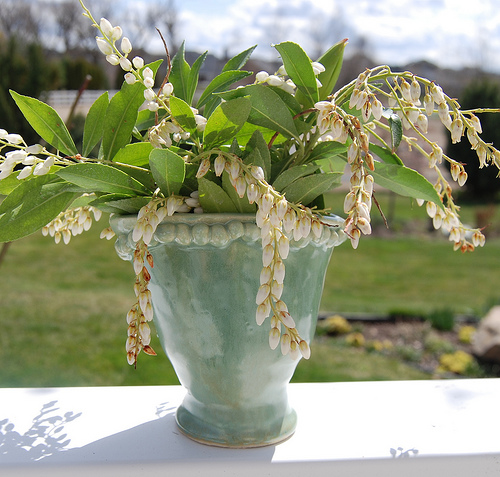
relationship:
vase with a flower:
[107, 209, 350, 451] [30, 151, 61, 181]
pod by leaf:
[191, 153, 215, 179] [53, 159, 158, 201]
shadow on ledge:
[0, 394, 76, 467] [1, 377, 496, 476]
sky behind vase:
[39, 0, 497, 72] [107, 209, 350, 451]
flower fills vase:
[30, 151, 61, 181] [107, 209, 350, 451]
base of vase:
[173, 399, 300, 451] [107, 209, 350, 451]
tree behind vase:
[41, 1, 87, 95] [107, 209, 350, 451]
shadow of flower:
[0, 394, 76, 467] [30, 151, 61, 181]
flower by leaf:
[30, 151, 61, 181] [53, 159, 158, 201]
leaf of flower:
[53, 159, 158, 201] [30, 151, 61, 181]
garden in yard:
[323, 317, 499, 375] [1, 198, 498, 388]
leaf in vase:
[53, 159, 158, 201] [107, 209, 350, 451]